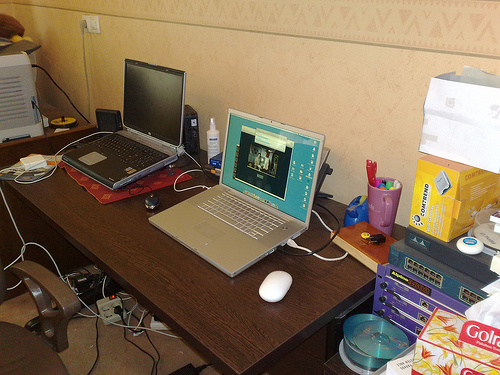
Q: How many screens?
A: Two.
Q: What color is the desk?
A: Brown.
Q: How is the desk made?
A: Of wood.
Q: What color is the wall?
A: Cream.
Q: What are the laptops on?
A: Desk.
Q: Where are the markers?
A: In cup.